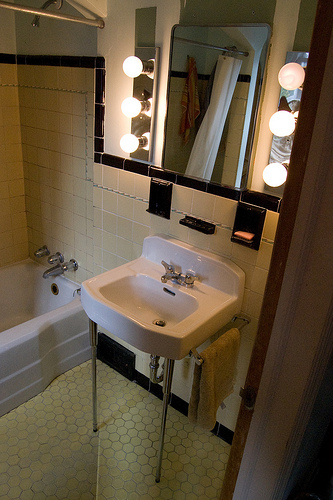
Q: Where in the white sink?
A: In the bathroom.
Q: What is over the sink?
A: A mirror.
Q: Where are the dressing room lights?
A: In the bathroom.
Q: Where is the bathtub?
A: In bathroom.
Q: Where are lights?
A: On both sides of the mirror.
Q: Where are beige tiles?
A: On the wall.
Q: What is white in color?
A: Sink.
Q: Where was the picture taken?
A: In a bathroom.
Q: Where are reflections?
A: On the mirror.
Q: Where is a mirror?
A: On the wall.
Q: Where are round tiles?
A: On the floor.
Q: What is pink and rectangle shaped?
A: Soap.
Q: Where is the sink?
A: Next to the tub.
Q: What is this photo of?
A: A room.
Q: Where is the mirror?
A: Above the sink.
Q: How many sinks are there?
A: One.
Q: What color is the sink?
A: White.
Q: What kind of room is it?
A: A bathroom.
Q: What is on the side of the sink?
A: A towel.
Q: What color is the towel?
A: Green.